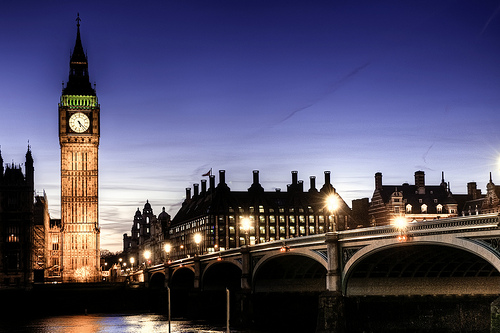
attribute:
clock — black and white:
[70, 113, 87, 132]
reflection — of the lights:
[125, 312, 178, 332]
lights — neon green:
[70, 56, 89, 68]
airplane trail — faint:
[274, 54, 372, 124]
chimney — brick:
[413, 170, 426, 186]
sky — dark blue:
[114, 12, 461, 150]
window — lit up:
[229, 235, 236, 248]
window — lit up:
[317, 214, 324, 224]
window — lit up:
[237, 215, 252, 230]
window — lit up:
[217, 213, 224, 222]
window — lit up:
[329, 215, 336, 224]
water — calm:
[6, 305, 268, 332]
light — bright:
[385, 211, 417, 231]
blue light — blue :
[100, 315, 124, 328]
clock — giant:
[68, 108, 97, 135]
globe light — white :
[189, 229, 206, 249]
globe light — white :
[156, 239, 177, 256]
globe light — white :
[141, 249, 154, 260]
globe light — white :
[127, 254, 138, 266]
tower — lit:
[61, 10, 99, 282]